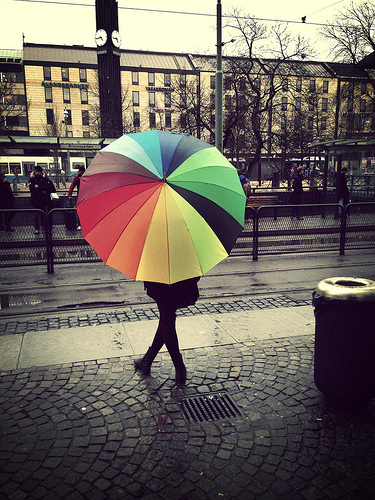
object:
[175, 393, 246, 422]
drain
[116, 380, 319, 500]
ground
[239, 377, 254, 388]
brick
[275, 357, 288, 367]
brick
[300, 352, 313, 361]
brick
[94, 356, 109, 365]
brick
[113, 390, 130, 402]
brick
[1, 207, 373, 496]
sidewalk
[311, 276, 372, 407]
sidewalkcan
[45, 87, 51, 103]
window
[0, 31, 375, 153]
building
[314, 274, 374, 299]
top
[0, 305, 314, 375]
slab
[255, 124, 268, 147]
ground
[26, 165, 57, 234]
man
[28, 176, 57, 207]
coat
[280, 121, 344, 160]
ground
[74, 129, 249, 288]
colorful umbrella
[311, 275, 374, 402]
trashcan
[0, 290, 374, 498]
brick walkway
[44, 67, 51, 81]
window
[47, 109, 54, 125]
window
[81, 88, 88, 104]
window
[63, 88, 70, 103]
window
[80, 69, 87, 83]
window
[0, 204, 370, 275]
metal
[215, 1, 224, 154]
pole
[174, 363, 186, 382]
boots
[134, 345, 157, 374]
boots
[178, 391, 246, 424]
metal grate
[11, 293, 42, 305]
puddle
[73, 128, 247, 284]
umbrella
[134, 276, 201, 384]
woman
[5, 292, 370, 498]
walkway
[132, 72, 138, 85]
window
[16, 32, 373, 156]
tan building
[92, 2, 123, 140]
tower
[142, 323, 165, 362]
leg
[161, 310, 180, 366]
leg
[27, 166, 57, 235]
person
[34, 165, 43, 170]
hat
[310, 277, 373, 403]
trash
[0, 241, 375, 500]
street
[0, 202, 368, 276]
fencing